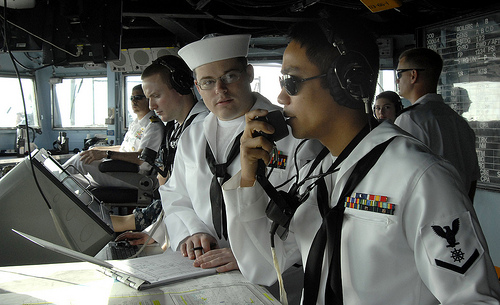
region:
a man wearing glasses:
[186, 46, 287, 143]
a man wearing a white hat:
[152, 25, 267, 123]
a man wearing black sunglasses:
[252, 45, 337, 155]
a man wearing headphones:
[115, 56, 205, 132]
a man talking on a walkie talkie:
[230, 26, 415, 221]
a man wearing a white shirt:
[255, 30, 465, 300]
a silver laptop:
[10, 195, 255, 295]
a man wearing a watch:
[62, 85, 192, 190]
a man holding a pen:
[145, 2, 260, 272]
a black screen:
[8, 0, 148, 77]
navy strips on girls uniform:
[347, 185, 395, 217]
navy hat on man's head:
[172, 22, 260, 68]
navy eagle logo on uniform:
[434, 214, 469, 248]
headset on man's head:
[315, 30, 379, 112]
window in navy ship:
[49, 72, 118, 136]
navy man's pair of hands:
[184, 223, 233, 283]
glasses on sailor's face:
[194, 68, 252, 90]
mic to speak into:
[245, 100, 302, 145]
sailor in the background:
[390, 51, 462, 151]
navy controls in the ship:
[26, 135, 146, 229]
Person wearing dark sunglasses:
[273, 70, 322, 97]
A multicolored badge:
[335, 186, 411, 223]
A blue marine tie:
[201, 141, 235, 248]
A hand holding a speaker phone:
[237, 100, 292, 209]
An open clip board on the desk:
[12, 223, 204, 298]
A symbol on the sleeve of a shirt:
[420, 215, 488, 280]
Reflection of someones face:
[439, 85, 496, 112]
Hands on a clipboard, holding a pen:
[172, 223, 239, 281]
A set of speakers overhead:
[118, 43, 160, 71]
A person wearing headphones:
[312, 30, 387, 99]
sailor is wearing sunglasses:
[253, 47, 320, 156]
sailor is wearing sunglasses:
[233, 60, 368, 141]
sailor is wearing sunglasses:
[252, 46, 392, 194]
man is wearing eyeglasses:
[166, 61, 263, 126]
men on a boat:
[82, 40, 499, 295]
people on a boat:
[111, 11, 496, 212]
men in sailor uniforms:
[64, 26, 499, 226]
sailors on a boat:
[93, 28, 410, 290]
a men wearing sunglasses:
[254, 22, 431, 198]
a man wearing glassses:
[164, 5, 237, 132]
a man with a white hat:
[194, 13, 279, 140]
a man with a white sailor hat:
[196, 16, 283, 130]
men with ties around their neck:
[122, 18, 499, 290]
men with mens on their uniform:
[274, 86, 454, 304]